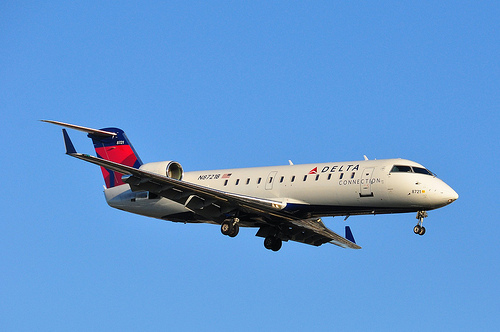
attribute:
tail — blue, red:
[38, 114, 144, 189]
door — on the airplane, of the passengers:
[356, 163, 383, 196]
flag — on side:
[219, 170, 234, 177]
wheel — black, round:
[220, 217, 233, 234]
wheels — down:
[217, 215, 239, 237]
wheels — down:
[262, 233, 283, 251]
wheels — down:
[411, 223, 427, 235]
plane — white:
[35, 102, 448, 244]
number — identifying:
[196, 171, 228, 185]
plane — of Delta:
[36, 95, 437, 270]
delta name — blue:
[317, 163, 365, 173]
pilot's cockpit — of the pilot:
[368, 139, 479, 196]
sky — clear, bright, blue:
[4, 2, 484, 328]